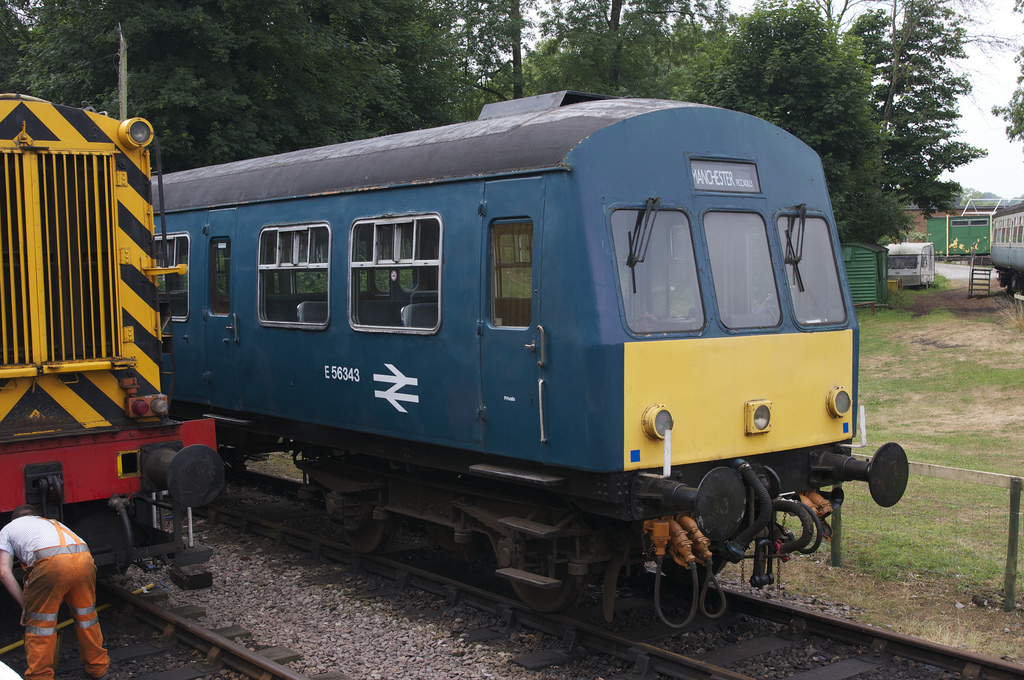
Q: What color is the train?
A: Mostly blue.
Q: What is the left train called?
A: A locomotive.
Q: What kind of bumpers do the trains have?
A: European.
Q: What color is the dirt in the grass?
A: Brown.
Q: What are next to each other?
A: The tracks.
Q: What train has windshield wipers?
A: The right one.